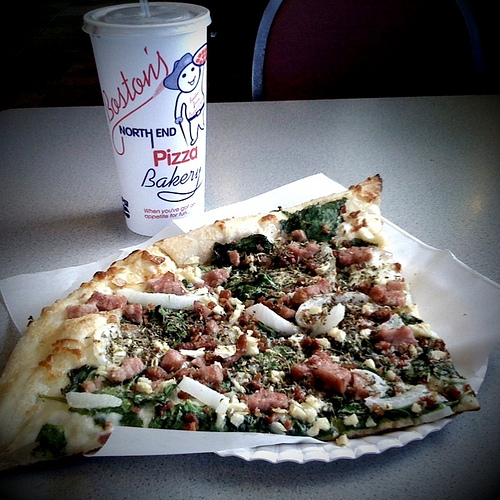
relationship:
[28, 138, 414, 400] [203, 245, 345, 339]
pizza with toppings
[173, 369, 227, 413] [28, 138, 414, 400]
onion on slice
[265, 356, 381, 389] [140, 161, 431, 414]
chunk of meat in pizza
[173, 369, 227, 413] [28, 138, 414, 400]
onion on pizza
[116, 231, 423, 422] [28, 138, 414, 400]
chunk on pizza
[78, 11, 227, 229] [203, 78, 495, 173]
soda on table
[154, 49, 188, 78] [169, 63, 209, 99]
hat on head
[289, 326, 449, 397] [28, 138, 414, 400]
meat on pizza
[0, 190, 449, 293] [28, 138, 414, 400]
plate under pizza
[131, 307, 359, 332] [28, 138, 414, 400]
vegetables on pizza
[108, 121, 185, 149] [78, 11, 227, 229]
writing on cup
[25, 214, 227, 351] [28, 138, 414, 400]
crust of pizza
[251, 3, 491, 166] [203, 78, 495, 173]
chair behind table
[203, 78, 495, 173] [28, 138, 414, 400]
table with food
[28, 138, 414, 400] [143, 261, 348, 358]
pizza has multiple toppings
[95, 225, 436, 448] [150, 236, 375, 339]
portions covered with toppings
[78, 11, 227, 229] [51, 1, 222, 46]
container has lid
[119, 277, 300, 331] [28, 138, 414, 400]
onions on pizza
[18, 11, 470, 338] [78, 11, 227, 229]
meal of pizza and beverage